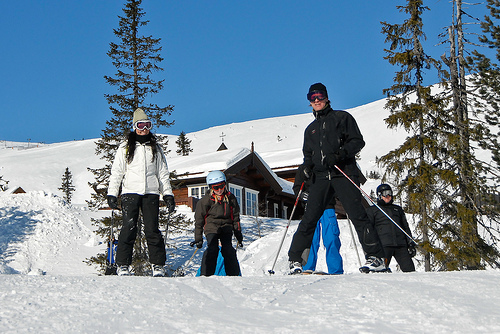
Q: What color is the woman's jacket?
A: White.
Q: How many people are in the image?
A: 5.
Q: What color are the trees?
A: Green.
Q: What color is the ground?
A: White.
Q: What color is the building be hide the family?
A: Brown.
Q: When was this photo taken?
A: Daytime.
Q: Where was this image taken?
A: Slopes.